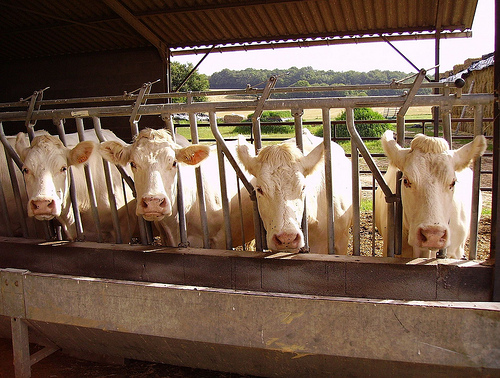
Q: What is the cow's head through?
A: A trough.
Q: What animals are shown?
A: Cows.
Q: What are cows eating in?
A: Trough.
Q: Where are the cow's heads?
A: Trough.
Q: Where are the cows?
A: Barn.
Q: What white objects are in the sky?
A: Clouds.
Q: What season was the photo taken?
A: Summer.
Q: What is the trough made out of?
A: Metal.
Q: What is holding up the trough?
A: Concrete.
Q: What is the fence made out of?
A: Metal.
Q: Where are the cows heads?
A: Between bars.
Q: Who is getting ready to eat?
A: Cows.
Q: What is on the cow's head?
A: Ears.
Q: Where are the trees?
A: Behind cows.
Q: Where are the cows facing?
A: Straight ahead.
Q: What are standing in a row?
A: 4 cows.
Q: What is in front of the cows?
A: A feeder.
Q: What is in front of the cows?
A: A feeder.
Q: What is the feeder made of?
A: Metal.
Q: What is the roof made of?
A: Tin.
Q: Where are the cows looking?
A: At the camera.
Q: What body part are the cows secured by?
A: Their necks.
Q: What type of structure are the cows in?
A: A barn.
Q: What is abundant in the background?
A: Trees.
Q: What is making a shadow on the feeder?
A: The bars.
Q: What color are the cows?
A: White.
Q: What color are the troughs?
A: Gray.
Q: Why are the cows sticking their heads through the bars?
A: They are trying to drink the water.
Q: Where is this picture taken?
A: On a farm.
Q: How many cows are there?
A: Four.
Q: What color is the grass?
A: Green.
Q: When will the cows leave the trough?
A: After they have finished drinking water.